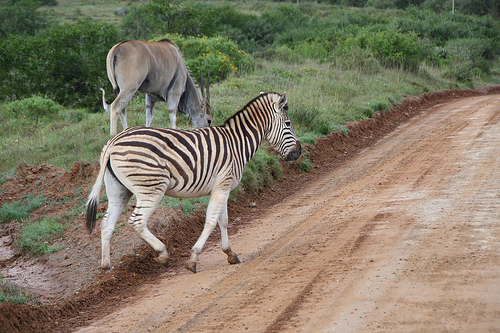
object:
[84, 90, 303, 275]
zebra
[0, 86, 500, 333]
dirt road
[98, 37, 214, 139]
antelope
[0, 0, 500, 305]
grass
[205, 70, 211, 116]
horn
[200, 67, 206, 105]
horn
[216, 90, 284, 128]
mane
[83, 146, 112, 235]
tail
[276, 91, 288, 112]
ear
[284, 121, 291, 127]
eye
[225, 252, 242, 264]
hoof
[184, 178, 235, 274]
leg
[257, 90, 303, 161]
head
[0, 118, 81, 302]
brush